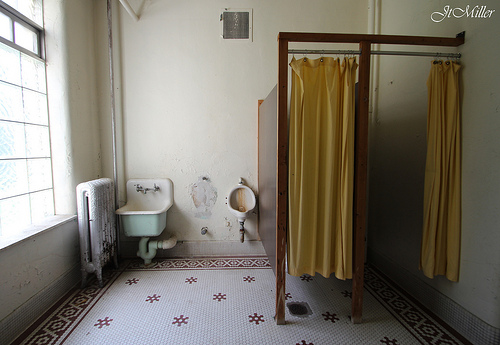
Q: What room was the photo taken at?
A: It was taken at the bathroom.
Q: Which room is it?
A: It is a bathroom.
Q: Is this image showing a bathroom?
A: Yes, it is showing a bathroom.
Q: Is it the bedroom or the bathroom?
A: It is the bathroom.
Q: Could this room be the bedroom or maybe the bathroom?
A: It is the bathroom.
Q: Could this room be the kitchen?
A: No, it is the bathroom.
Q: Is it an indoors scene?
A: Yes, it is indoors.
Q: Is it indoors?
A: Yes, it is indoors.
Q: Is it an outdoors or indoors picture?
A: It is indoors.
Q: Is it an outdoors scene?
A: No, it is indoors.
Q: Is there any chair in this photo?
A: No, there are no chairs.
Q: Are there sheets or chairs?
A: No, there are no chairs or sheets.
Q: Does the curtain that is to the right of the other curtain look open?
A: Yes, the curtain is open.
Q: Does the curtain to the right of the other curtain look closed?
A: No, the curtain is open.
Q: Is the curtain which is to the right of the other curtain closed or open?
A: The curtain is open.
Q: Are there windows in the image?
A: Yes, there is a window.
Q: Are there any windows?
A: Yes, there is a window.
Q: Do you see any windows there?
A: Yes, there is a window.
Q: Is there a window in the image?
A: Yes, there is a window.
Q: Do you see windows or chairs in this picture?
A: Yes, there is a window.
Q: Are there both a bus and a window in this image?
A: No, there is a window but no buses.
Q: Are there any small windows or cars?
A: Yes, there is a small window.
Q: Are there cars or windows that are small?
A: Yes, the window is small.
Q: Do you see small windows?
A: Yes, there is a small window.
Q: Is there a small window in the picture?
A: Yes, there is a small window.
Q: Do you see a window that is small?
A: Yes, there is a window that is small.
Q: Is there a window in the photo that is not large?
A: Yes, there is a small window.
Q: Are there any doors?
A: No, there are no doors.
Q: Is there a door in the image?
A: No, there are no doors.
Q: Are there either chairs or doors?
A: No, there are no doors or chairs.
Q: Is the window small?
A: Yes, the window is small.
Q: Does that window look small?
A: Yes, the window is small.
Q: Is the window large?
A: No, the window is small.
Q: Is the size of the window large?
A: No, the window is small.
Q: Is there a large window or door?
A: No, there is a window but it is small.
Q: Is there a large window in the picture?
A: No, there is a window but it is small.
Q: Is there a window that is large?
A: No, there is a window but it is small.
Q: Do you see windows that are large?
A: No, there is a window but it is small.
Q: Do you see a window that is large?
A: No, there is a window but it is small.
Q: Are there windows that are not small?
A: No, there is a window but it is small.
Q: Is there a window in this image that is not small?
A: No, there is a window but it is small.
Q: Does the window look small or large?
A: The window is small.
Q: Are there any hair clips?
A: No, there are no hair clips.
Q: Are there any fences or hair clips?
A: No, there are no hair clips or fences.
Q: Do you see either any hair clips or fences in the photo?
A: No, there are no hair clips or fences.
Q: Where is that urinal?
A: The urinal is in the bathroom.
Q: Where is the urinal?
A: The urinal is in the bathroom.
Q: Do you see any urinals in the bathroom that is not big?
A: Yes, there is a urinal in the bathroom.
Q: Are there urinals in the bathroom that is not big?
A: Yes, there is a urinal in the bathroom.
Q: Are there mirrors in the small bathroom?
A: No, there is a urinal in the bathroom.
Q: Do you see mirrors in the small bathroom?
A: No, there is a urinal in the bathroom.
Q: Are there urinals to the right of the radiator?
A: Yes, there is a urinal to the right of the radiator.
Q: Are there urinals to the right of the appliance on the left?
A: Yes, there is a urinal to the right of the radiator.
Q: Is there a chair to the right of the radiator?
A: No, there is a urinal to the right of the radiator.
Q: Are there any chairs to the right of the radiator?
A: No, there is a urinal to the right of the radiator.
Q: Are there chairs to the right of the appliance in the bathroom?
A: No, there is a urinal to the right of the radiator.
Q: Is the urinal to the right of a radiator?
A: Yes, the urinal is to the right of a radiator.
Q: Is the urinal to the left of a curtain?
A: Yes, the urinal is to the left of a curtain.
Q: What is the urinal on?
A: The urinal is on the wall.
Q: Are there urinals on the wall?
A: Yes, there is a urinal on the wall.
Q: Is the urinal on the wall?
A: Yes, the urinal is on the wall.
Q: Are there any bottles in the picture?
A: No, there are no bottles.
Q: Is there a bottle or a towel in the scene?
A: No, there are no bottles or towels.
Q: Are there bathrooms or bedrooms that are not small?
A: No, there is a bathroom but it is small.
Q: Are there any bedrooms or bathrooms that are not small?
A: No, there is a bathroom but it is small.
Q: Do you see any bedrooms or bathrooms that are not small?
A: No, there is a bathroom but it is small.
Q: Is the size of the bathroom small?
A: Yes, the bathroom is small.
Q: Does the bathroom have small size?
A: Yes, the bathroom is small.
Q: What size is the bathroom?
A: The bathroom is small.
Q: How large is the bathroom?
A: The bathroom is small.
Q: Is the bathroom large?
A: No, the bathroom is small.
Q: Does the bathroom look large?
A: No, the bathroom is small.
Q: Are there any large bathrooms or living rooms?
A: No, there is a bathroom but it is small.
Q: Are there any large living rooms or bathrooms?
A: No, there is a bathroom but it is small.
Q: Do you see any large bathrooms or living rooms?
A: No, there is a bathroom but it is small.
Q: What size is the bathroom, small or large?
A: The bathroom is small.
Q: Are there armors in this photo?
A: No, there are no armors.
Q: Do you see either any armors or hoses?
A: No, there are no armors or hoses.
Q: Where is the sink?
A: The sink is in the bathroom.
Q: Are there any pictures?
A: No, there are no pictures.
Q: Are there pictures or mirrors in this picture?
A: No, there are no pictures or mirrors.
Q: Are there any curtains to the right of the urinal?
A: Yes, there is a curtain to the right of the urinal.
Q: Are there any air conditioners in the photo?
A: No, there are no air conditioners.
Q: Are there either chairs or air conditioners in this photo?
A: No, there are no air conditioners or chairs.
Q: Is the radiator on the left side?
A: Yes, the radiator is on the left of the image.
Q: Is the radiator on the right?
A: No, the radiator is on the left of the image.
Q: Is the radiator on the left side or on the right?
A: The radiator is on the left of the image.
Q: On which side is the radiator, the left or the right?
A: The radiator is on the left of the image.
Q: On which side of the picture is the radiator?
A: The radiator is on the left of the image.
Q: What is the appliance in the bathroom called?
A: The appliance is a radiator.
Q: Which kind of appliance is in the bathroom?
A: The appliance is a radiator.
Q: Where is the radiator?
A: The radiator is in the bathroom.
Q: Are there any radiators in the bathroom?
A: Yes, there is a radiator in the bathroom.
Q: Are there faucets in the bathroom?
A: No, there is a radiator in the bathroom.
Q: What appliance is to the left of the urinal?
A: The appliance is a radiator.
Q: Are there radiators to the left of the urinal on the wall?
A: Yes, there is a radiator to the left of the urinal.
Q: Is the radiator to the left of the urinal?
A: Yes, the radiator is to the left of the urinal.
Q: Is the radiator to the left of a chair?
A: No, the radiator is to the left of the urinal.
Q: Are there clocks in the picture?
A: No, there are no clocks.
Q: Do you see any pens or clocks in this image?
A: No, there are no clocks or pens.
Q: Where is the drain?
A: The drain is in the bathroom.